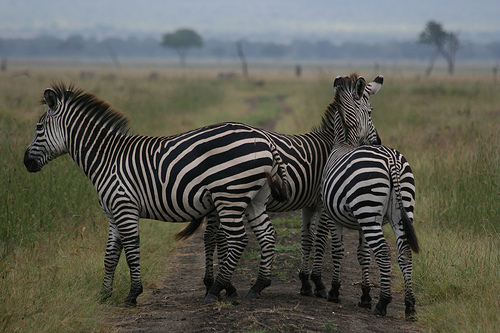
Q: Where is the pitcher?
A: On the pitcher's mound.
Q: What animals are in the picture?
A: Zebras.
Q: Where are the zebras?
A: In a large field in the wild.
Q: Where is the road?
A: In the center of the picture where the zebras stand.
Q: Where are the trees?
A: They are standing far away in the background.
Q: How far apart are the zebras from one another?
A: The zebras are very close together.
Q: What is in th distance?
A: Trees and grasses.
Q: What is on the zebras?
A: Black and white strips.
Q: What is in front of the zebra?
A: Brown and green grasses.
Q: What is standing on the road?
A: A zebra.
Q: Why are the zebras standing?
A: Looking to see where to go.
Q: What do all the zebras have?
A: Black and white strips.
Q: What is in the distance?
A: Lots of trees.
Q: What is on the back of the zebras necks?
A: A mane.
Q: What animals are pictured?
A: Zebras.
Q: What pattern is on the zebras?
A: Stripes.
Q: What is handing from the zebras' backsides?
A: Tails.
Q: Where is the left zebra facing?
A: Left.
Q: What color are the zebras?
A: Black and white.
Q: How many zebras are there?
A: Three.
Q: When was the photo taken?
A: Daytime.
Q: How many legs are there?
A: Twelve.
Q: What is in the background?
A: Trees.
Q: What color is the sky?
A: Blue.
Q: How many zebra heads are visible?
A: Two.